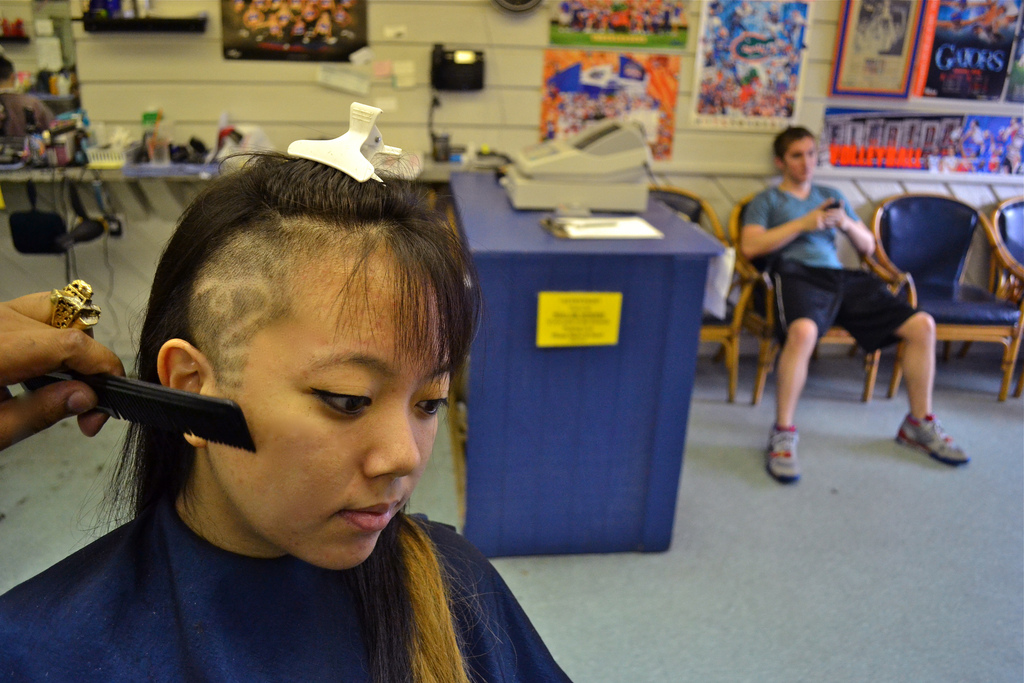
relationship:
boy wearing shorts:
[738, 106, 985, 504] [759, 247, 919, 358]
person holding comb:
[0, 152, 571, 678] [64, 360, 250, 453]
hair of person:
[86, 147, 476, 530] [0, 161, 544, 678]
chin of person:
[310, 528, 384, 567] [0, 161, 544, 678]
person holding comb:
[4, 278, 115, 464] [64, 360, 250, 453]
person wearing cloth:
[0, 161, 544, 678] [4, 509, 569, 680]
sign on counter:
[536, 289, 621, 348] [451, 170, 722, 557]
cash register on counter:
[503, 106, 663, 213] [455, 177, 727, 558]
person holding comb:
[0, 278, 123, 451] [26, 360, 256, 449]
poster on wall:
[536, 43, 677, 165] [0, 2, 1020, 296]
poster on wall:
[700, 6, 800, 121] [4, 2, 1016, 359]